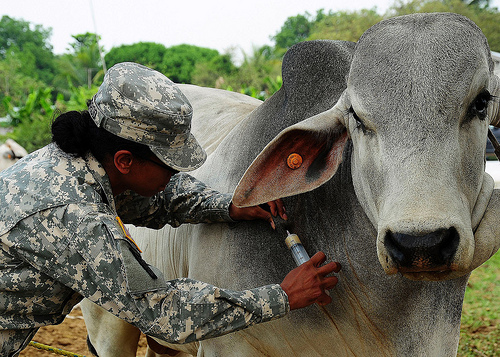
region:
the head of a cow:
[221, 24, 498, 284]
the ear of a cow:
[213, 66, 407, 261]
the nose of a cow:
[356, 212, 470, 287]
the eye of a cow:
[431, 75, 499, 120]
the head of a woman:
[48, 60, 243, 212]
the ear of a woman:
[96, 141, 145, 186]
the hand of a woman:
[266, 245, 346, 310]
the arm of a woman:
[38, 183, 435, 342]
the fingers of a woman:
[293, 230, 349, 305]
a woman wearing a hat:
[44, 0, 278, 197]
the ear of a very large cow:
[230, 103, 349, 215]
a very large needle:
[277, 207, 318, 285]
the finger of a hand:
[307, 248, 326, 266]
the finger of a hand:
[317, 258, 339, 273]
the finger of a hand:
[322, 275, 340, 285]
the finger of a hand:
[315, 288, 328, 302]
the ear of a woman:
[113, 149, 129, 170]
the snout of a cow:
[380, 223, 465, 271]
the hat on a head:
[89, 64, 206, 174]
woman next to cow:
[0, 60, 341, 352]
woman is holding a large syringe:
[280, 225, 325, 290]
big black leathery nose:
[385, 225, 455, 275]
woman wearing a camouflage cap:
[85, 60, 205, 170]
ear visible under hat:
[110, 145, 130, 170]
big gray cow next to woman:
[77, 10, 492, 352]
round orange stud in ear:
[285, 151, 298, 167]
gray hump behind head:
[278, 34, 353, 96]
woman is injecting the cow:
[3, 64, 343, 355]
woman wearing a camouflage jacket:
[1, 139, 289, 354]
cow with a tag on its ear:
[279, 148, 312, 175]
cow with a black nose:
[384, 210, 457, 283]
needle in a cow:
[271, 218, 342, 306]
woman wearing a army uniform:
[23, 75, 320, 342]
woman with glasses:
[99, 137, 195, 190]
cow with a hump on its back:
[253, 39, 390, 134]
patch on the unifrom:
[107, 214, 143, 270]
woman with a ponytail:
[26, 97, 129, 184]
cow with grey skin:
[218, 62, 475, 267]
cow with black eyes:
[464, 85, 494, 129]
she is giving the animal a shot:
[0, 61, 350, 348]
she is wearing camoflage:
[0, 51, 371, 352]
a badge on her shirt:
[107, 207, 162, 284]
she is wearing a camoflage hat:
[82, 52, 211, 168]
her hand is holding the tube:
[278, 223, 329, 313]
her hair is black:
[39, 99, 126, 161]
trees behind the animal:
[10, 8, 492, 163]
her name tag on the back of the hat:
[81, 92, 106, 126]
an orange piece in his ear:
[281, 149, 308, 169]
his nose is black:
[381, 219, 461, 276]